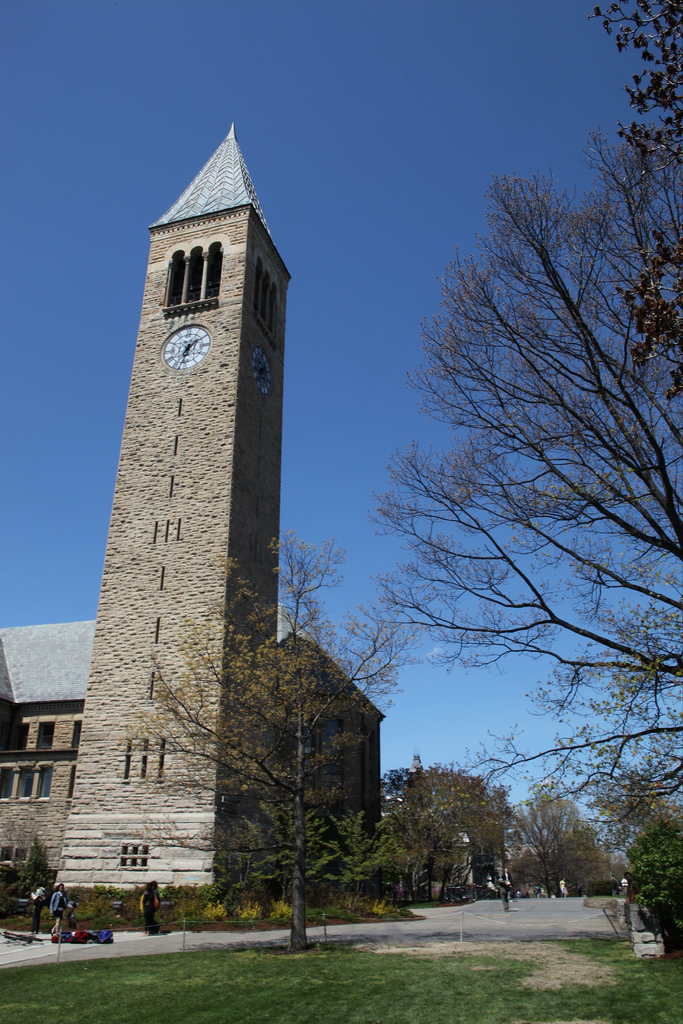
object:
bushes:
[373, 889, 399, 918]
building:
[0, 115, 397, 945]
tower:
[45, 110, 296, 910]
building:
[0, 605, 388, 921]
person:
[30, 884, 48, 934]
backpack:
[39, 889, 46, 902]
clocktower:
[56, 112, 304, 900]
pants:
[499, 885, 513, 913]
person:
[138, 874, 154, 939]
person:
[46, 878, 74, 943]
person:
[495, 866, 522, 917]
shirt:
[50, 891, 73, 915]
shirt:
[141, 892, 159, 916]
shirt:
[497, 871, 510, 893]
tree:
[120, 528, 423, 955]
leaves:
[354, 605, 366, 617]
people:
[140, 882, 156, 933]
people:
[50, 881, 71, 934]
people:
[28, 882, 41, 940]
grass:
[371, 945, 623, 995]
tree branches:
[360, 124, 682, 849]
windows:
[34, 759, 52, 805]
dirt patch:
[549, 955, 600, 983]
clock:
[158, 321, 216, 375]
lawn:
[296, 969, 444, 1018]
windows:
[162, 240, 222, 317]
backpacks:
[93, 928, 121, 952]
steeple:
[143, 117, 293, 292]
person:
[28, 877, 49, 938]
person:
[150, 878, 163, 941]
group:
[23, 862, 173, 955]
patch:
[511, 967, 558, 994]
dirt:
[487, 937, 572, 958]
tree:
[374, 137, 682, 802]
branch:
[466, 726, 643, 785]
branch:
[421, 621, 591, 696]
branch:
[364, 463, 560, 651]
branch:
[571, 192, 616, 286]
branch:
[425, 320, 522, 414]